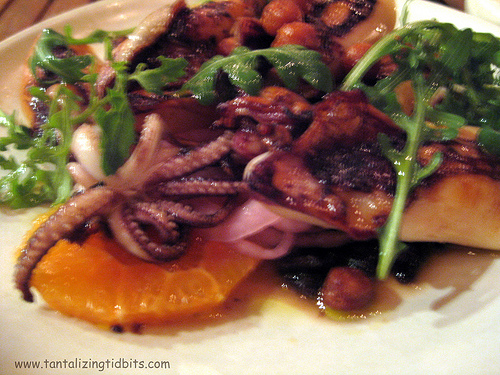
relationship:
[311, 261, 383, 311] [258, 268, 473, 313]
berry lies in juice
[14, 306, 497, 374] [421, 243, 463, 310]
plate has shadow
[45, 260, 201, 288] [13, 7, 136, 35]
hot dogs on table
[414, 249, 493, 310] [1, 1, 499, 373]
shadow on plate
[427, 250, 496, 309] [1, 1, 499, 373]
sauce on plate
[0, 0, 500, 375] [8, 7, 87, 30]
plate has edge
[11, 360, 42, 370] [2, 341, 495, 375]
ws on a background